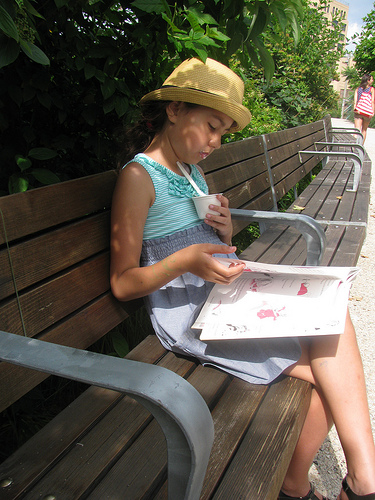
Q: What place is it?
A: It is a park.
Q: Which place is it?
A: It is a park.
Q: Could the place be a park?
A: Yes, it is a park.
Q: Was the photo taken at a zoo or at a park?
A: It was taken at a park.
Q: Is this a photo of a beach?
A: No, the picture is showing a park.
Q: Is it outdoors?
A: Yes, it is outdoors.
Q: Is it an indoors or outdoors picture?
A: It is outdoors.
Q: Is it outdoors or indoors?
A: It is outdoors.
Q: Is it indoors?
A: No, it is outdoors.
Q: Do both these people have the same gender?
A: Yes, all the people are female.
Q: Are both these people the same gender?
A: Yes, all the people are female.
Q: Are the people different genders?
A: No, all the people are female.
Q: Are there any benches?
A: Yes, there is a bench.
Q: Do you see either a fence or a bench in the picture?
A: Yes, there is a bench.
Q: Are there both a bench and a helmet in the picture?
A: No, there is a bench but no helmets.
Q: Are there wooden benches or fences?
A: Yes, there is a wood bench.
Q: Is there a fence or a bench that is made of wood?
A: Yes, the bench is made of wood.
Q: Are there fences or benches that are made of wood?
A: Yes, the bench is made of wood.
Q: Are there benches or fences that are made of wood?
A: Yes, the bench is made of wood.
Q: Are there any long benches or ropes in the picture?
A: Yes, there is a long bench.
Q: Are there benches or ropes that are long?
A: Yes, the bench is long.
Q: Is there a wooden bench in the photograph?
A: Yes, there is a wood bench.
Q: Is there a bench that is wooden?
A: Yes, there is a bench that is wooden.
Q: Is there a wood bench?
A: Yes, there is a bench that is made of wood.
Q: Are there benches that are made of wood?
A: Yes, there is a bench that is made of wood.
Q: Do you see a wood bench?
A: Yes, there is a bench that is made of wood.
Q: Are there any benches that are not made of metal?
A: Yes, there is a bench that is made of wood.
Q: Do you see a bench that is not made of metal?
A: Yes, there is a bench that is made of wood.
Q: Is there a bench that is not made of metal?
A: Yes, there is a bench that is made of wood.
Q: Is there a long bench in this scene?
A: Yes, there is a long bench.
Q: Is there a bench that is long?
A: Yes, there is a bench that is long.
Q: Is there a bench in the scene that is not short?
A: Yes, there is a long bench.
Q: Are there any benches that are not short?
A: Yes, there is a long bench.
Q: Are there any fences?
A: No, there are no fences.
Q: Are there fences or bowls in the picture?
A: No, there are no fences or bowls.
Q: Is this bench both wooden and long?
A: Yes, the bench is wooden and long.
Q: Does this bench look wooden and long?
A: Yes, the bench is wooden and long.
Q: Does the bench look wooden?
A: Yes, the bench is wooden.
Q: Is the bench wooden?
A: Yes, the bench is wooden.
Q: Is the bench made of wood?
A: Yes, the bench is made of wood.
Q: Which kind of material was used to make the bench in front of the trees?
A: The bench is made of wood.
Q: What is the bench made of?
A: The bench is made of wood.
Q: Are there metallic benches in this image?
A: No, there is a bench but it is wooden.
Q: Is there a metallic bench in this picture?
A: No, there is a bench but it is wooden.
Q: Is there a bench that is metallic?
A: No, there is a bench but it is wooden.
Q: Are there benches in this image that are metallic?
A: No, there is a bench but it is wooden.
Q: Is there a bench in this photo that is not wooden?
A: No, there is a bench but it is wooden.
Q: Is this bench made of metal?
A: No, the bench is made of wood.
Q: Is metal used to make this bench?
A: No, the bench is made of wood.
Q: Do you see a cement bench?
A: No, there is a bench but it is made of wood.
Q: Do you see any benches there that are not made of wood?
A: No, there is a bench but it is made of wood.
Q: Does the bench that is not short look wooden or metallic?
A: The bench is wooden.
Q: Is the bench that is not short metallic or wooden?
A: The bench is wooden.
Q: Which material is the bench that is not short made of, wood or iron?
A: The bench is made of wood.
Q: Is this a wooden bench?
A: Yes, this is a wooden bench.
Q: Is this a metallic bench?
A: No, this is a wooden bench.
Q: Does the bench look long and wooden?
A: Yes, the bench is long and wooden.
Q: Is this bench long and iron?
A: No, the bench is long but wooden.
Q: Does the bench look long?
A: Yes, the bench is long.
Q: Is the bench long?
A: Yes, the bench is long.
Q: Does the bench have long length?
A: Yes, the bench is long.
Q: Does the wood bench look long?
A: Yes, the bench is long.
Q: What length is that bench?
A: The bench is long.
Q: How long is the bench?
A: The bench is long.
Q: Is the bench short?
A: No, the bench is long.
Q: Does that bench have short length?
A: No, the bench is long.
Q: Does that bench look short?
A: No, the bench is long.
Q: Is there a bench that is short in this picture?
A: No, there is a bench but it is long.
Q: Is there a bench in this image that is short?
A: No, there is a bench but it is long.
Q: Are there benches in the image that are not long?
A: No, there is a bench but it is long.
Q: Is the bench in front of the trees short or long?
A: The bench is long.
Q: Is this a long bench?
A: Yes, this is a long bench.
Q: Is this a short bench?
A: No, this is a long bench.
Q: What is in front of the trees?
A: The bench is in front of the trees.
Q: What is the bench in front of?
A: The bench is in front of the trees.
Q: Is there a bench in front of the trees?
A: Yes, there is a bench in front of the trees.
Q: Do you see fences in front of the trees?
A: No, there is a bench in front of the trees.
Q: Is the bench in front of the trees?
A: Yes, the bench is in front of the trees.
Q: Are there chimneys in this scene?
A: No, there are no chimneys.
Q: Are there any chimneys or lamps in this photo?
A: No, there are no chimneys or lamps.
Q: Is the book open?
A: Yes, the book is open.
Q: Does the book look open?
A: Yes, the book is open.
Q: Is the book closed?
A: No, the book is open.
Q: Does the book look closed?
A: No, the book is open.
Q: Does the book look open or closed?
A: The book is open.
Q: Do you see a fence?
A: No, there are no fences.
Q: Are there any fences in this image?
A: No, there are no fences.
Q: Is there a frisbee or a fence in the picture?
A: No, there are no fences or frisbees.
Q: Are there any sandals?
A: Yes, there are sandals.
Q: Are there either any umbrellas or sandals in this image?
A: Yes, there are sandals.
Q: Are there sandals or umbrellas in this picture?
A: Yes, there are sandals.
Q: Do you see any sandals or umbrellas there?
A: Yes, there are sandals.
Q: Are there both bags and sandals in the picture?
A: Yes, there are both sandals and a bag.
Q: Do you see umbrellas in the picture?
A: No, there are no umbrellas.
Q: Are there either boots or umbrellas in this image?
A: No, there are no umbrellas or boots.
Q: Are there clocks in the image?
A: No, there are no clocks.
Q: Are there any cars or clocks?
A: No, there are no clocks or cars.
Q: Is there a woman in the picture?
A: Yes, there is a woman.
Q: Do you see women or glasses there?
A: Yes, there is a woman.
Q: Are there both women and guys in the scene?
A: No, there is a woman but no guys.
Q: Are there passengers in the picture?
A: No, there are no passengers.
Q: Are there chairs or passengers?
A: No, there are no passengers or chairs.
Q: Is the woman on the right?
A: Yes, the woman is on the right of the image.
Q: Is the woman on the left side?
A: No, the woman is on the right of the image.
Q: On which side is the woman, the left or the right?
A: The woman is on the right of the image.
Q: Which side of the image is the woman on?
A: The woman is on the right of the image.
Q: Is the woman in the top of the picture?
A: Yes, the woman is in the top of the image.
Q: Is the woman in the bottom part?
A: No, the woman is in the top of the image.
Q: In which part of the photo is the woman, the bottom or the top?
A: The woman is in the top of the image.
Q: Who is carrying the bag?
A: The woman is carrying the bag.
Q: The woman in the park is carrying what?
A: The woman is carrying a bag.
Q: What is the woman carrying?
A: The woman is carrying a bag.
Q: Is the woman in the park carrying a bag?
A: Yes, the woman is carrying a bag.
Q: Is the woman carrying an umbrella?
A: No, the woman is carrying a bag.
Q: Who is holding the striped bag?
A: The woman is holding the bag.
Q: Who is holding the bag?
A: The woman is holding the bag.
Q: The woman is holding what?
A: The woman is holding the bag.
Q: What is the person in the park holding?
A: The woman is holding the bag.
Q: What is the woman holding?
A: The woman is holding the bag.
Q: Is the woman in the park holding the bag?
A: Yes, the woman is holding the bag.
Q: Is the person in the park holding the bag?
A: Yes, the woman is holding the bag.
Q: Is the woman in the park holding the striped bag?
A: Yes, the woman is holding the bag.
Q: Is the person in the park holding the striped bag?
A: Yes, the woman is holding the bag.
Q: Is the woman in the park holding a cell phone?
A: No, the woman is holding the bag.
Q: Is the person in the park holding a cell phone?
A: No, the woman is holding the bag.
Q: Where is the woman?
A: The woman is in the park.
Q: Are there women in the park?
A: Yes, there is a woman in the park.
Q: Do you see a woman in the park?
A: Yes, there is a woman in the park.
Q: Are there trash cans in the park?
A: No, there is a woman in the park.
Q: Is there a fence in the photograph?
A: No, there are no fences.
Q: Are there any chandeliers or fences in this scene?
A: No, there are no fences or chandeliers.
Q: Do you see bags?
A: Yes, there is a bag.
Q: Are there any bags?
A: Yes, there is a bag.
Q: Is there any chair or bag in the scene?
A: Yes, there is a bag.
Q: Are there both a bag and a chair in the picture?
A: No, there is a bag but no chairs.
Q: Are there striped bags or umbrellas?
A: Yes, there is a striped bag.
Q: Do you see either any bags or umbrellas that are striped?
A: Yes, the bag is striped.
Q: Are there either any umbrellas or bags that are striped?
A: Yes, the bag is striped.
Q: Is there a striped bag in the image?
A: Yes, there is a striped bag.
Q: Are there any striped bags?
A: Yes, there is a striped bag.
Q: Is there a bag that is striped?
A: Yes, there is a bag that is striped.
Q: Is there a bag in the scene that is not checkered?
A: Yes, there is a striped bag.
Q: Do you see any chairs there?
A: No, there are no chairs.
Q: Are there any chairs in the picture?
A: No, there are no chairs.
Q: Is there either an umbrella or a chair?
A: No, there are no chairs or umbrellas.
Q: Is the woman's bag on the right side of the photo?
A: Yes, the bag is on the right of the image.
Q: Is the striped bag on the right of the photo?
A: Yes, the bag is on the right of the image.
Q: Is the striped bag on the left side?
A: No, the bag is on the right of the image.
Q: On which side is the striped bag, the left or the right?
A: The bag is on the right of the image.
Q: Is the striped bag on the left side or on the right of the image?
A: The bag is on the right of the image.